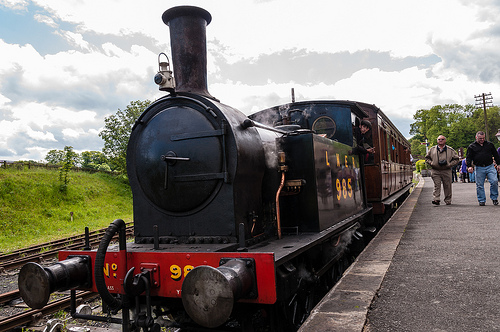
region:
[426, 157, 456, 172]
Man has his hands in his jacket pocket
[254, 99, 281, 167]
Smoke coming out of engine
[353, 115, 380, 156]
Man hanging out window of train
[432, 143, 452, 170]
Camera around man's neck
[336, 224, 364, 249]
Smoke coming from underneath train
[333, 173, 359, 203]
Train number is 985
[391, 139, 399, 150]
Blue light coming from train window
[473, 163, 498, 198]
Man has on blue jeans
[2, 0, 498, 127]
Clouds fill the sky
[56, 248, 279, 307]
Train has red fender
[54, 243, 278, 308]
Red and yellow front part of train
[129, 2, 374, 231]
Black front of train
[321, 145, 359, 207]
yellow letters on the side of train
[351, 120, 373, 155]
train conductor poking his head out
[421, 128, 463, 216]
Man walking down the sidewalk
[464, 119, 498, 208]
man walking down the sidwalk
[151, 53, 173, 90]
Little white lantern in front of train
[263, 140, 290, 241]
Copper steam pipe on train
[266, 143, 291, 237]
Steam pipe shooting out steam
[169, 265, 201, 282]
yellow "98" on red part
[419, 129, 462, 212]
person walking near a train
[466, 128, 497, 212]
person walking near a train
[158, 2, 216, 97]
smoke stack on a train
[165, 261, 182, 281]
number painted on a train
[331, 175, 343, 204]
number painted on a train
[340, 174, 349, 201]
number painted on a train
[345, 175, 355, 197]
number painted on a train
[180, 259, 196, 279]
number painted on a train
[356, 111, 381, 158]
person inside of a train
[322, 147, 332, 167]
letter painted on the side of a train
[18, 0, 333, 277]
Train parked in the railway station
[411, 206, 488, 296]
Platform of the railway station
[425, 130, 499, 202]
People walking on the platform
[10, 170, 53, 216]
Green color grass near the track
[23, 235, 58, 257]
Train track near the platform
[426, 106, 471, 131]
Trees with green leaves and branches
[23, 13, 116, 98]
Blue color sky with clouds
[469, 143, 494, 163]
A person wearing black color fullhand shirt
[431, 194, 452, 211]
Pair of shoes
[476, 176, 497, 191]
A person wearing blue color jean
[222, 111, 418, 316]
this is a trainq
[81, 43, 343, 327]
the train is black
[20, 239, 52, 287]
this is a train track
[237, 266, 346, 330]
this is a curb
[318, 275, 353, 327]
the curb is stone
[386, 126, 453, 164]
this is a group of people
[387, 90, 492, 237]
these are two men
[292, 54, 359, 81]
this is a cloud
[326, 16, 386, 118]
the cloud is white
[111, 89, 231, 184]
this is the front of the train